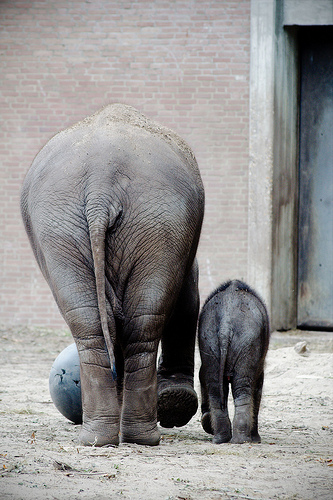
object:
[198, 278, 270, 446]
elephant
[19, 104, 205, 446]
elephant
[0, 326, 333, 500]
ground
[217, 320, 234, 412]
tail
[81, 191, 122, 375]
tail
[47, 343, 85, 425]
ball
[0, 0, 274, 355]
wall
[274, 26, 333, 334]
door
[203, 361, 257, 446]
legs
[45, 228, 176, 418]
legs